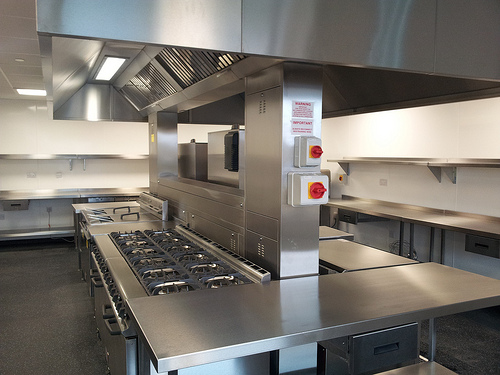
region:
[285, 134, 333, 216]
red buttons between ovens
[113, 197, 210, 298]
ovens have black covers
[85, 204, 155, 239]
black handles on frying machines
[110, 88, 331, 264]
steel walls to cooking line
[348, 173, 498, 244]
steel counter in background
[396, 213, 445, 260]
steel pipes under counter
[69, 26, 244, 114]
steel fume hood over ovens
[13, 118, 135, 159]
walls above counters are white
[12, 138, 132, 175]
steel shelf on wall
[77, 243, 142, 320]
black dials on ovens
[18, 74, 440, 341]
A stainless steal kitchen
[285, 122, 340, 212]
Knobs on a panel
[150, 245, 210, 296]
Cooking burners on a stove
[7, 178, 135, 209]
Steal counter in the back ground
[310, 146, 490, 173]
Shelves on the back wall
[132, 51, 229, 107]
Vents over the stove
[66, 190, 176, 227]
Deep fry well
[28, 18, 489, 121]
Roof over the stove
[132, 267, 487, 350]
Steel table by the stove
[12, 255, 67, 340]
Black tile floor in kitchen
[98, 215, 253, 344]
multiple stove units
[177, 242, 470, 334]
shiny new black countertops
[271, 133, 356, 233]
two orange buttons on the wall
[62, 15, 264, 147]
large vents in the ceiling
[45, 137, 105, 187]
white wall behind the shelves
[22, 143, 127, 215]
stainless steel shelves in the kitchen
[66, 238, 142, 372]
ovens underneath the counters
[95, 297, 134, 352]
black handles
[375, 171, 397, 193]
plug in on the wall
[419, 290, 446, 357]
metal pole holding the counter up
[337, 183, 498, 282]
stainless steel counter tops in a kitchen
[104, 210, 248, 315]
multi unit range set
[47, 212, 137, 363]
ovens beneath the ranges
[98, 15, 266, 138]
large ventilation system in the kitchen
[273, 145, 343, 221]
orange switches on the wall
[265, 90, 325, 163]
a red and white warning label on the wall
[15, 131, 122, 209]
white wall behind the counter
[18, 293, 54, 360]
black floor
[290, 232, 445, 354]
shiny new countertop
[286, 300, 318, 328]
part of a surface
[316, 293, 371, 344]
edge of a surafce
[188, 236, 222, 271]
part of a cooker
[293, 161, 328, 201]
part of a switch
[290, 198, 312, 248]
part of an edge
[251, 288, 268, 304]
part of a surface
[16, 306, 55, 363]
part of a floor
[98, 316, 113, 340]
part of a handle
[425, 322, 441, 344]
part of a stand